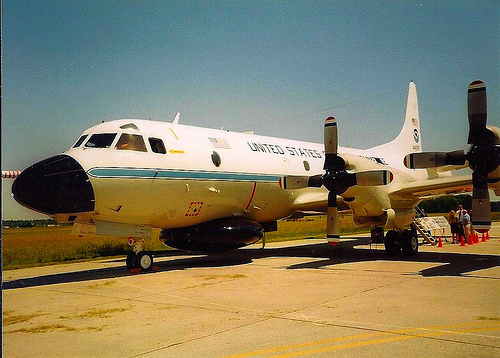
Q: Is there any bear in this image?
A: No, there are no bears.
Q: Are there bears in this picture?
A: No, there are no bears.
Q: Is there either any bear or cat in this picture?
A: No, there are no bears or cats.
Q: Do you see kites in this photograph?
A: No, there are no kites.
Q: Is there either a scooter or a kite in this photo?
A: No, there are no kites or scooters.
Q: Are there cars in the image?
A: No, there are no cars.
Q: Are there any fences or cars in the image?
A: No, there are no cars or fences.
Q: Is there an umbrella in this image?
A: No, there are no umbrellas.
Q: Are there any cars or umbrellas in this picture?
A: No, there are no umbrellas or cars.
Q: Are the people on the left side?
A: No, the people are on the right of the image.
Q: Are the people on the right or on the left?
A: The people are on the right of the image.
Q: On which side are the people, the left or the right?
A: The people are on the right of the image.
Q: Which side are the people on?
A: The people are on the right of the image.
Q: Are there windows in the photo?
A: Yes, there is a window.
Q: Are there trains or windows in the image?
A: Yes, there is a window.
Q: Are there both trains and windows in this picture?
A: No, there is a window but no trains.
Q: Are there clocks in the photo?
A: No, there are no clocks.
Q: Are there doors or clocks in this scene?
A: No, there are no clocks or doors.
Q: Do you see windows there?
A: Yes, there is a window.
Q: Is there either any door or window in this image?
A: Yes, there is a window.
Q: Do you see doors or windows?
A: Yes, there is a window.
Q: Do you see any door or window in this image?
A: Yes, there is a window.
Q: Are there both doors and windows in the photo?
A: No, there is a window but no doors.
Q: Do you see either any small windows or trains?
A: Yes, there is a small window.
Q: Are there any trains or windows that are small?
A: Yes, the window is small.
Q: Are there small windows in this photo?
A: Yes, there is a small window.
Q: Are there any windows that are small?
A: Yes, there is a window that is small.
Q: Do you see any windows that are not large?
A: Yes, there is a small window.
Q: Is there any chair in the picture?
A: No, there are no chairs.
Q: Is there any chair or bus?
A: No, there are no chairs or buses.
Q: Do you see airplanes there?
A: Yes, there is an airplane.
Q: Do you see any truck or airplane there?
A: Yes, there is an airplane.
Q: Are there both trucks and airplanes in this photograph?
A: No, there is an airplane but no trucks.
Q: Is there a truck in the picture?
A: No, there are no trucks.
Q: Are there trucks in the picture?
A: No, there are no trucks.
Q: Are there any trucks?
A: No, there are no trucks.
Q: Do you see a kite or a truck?
A: No, there are no trucks or kites.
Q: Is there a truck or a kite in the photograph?
A: No, there are no trucks or kites.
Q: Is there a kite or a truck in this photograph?
A: No, there are no trucks or kites.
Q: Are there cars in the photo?
A: No, there are no cars.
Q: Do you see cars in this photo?
A: No, there are no cars.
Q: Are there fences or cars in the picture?
A: No, there are no cars or fences.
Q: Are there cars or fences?
A: No, there are no cars or fences.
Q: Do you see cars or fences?
A: No, there are no cars or fences.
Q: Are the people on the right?
A: Yes, the people are on the right of the image.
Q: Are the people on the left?
A: No, the people are on the right of the image.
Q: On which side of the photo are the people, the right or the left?
A: The people are on the right of the image.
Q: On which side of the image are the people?
A: The people are on the right of the image.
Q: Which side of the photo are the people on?
A: The people are on the right of the image.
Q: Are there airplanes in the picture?
A: Yes, there is an airplane.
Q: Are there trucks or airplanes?
A: Yes, there is an airplane.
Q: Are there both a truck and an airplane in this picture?
A: No, there is an airplane but no trucks.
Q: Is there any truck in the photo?
A: No, there are no trucks.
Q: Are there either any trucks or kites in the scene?
A: No, there are no trucks or kites.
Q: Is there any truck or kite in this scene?
A: No, there are no trucks or kites.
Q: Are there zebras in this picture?
A: No, there are no zebras.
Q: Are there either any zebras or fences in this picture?
A: No, there are no zebras or fences.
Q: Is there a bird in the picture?
A: No, there are no birds.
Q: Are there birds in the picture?
A: No, there are no birds.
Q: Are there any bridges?
A: Yes, there is a bridge.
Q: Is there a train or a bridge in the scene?
A: Yes, there is a bridge.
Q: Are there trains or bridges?
A: Yes, there is a bridge.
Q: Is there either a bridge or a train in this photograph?
A: Yes, there is a bridge.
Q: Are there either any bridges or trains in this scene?
A: Yes, there is a bridge.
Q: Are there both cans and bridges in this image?
A: No, there is a bridge but no cans.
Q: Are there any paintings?
A: No, there are no paintings.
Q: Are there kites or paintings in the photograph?
A: No, there are no paintings or kites.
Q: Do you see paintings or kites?
A: No, there are no paintings or kites.